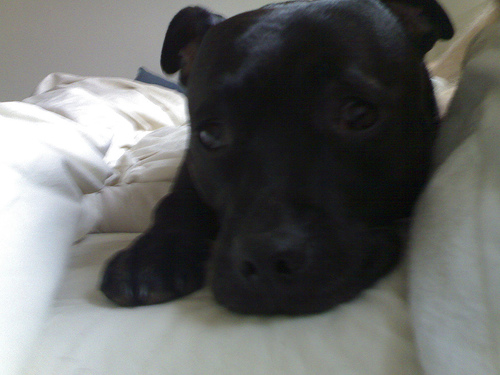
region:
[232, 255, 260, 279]
black nostril on dog's face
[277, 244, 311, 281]
round hole in dog's nostril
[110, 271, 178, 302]
black paws on dog's foot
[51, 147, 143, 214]
white creases in dog's bed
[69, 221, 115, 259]
edge of dog's bed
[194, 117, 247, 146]
dog's black eye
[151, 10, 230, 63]
dog's black floppy ear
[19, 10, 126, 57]
light gray wall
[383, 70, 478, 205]
side of dog's face resting on bed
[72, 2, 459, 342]
large black shaggy dog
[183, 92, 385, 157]
dark sad eyes of blurry puppy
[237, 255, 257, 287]
shadowed black+blurry nostril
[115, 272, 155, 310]
light reflecting off 2 dog's nails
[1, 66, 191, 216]
light reflecting off crumpled white bedding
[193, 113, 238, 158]
light reflecting on black puppy eye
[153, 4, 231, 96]
curled sweet puppy ear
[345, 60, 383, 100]
puppy eyebrow is slightly lighter than surrounding fur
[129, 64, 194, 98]
dark colored pillow in the photo's distance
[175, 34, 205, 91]
dark brown near ear of black puppy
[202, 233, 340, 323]
a black puppy's small muzzle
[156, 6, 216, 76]
The dog's left ear.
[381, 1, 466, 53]
The dog's right ear.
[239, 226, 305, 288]
The dog's nose and nostrils.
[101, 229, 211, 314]
The dog's left paw and nails.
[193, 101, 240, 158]
The black dog's left eye.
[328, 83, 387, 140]
The black dog's right eye.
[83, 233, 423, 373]
The white sheet the dog's paw and mouth is resting on.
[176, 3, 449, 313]
The black dog's head resting on the bed.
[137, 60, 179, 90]
The dark blue pillow in the background.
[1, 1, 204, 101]
The gray wall in the background.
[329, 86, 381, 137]
the right eye of a dog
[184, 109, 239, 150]
the left eye of a dog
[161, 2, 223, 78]
the ear of a dog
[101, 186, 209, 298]
the leg of a dog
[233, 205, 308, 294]
the nose of a dog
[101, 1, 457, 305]
a cute black dog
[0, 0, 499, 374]
a dog in a bed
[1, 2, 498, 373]
a bed with white sheets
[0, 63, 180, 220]
pillows in a bed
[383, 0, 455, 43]
the right ear of a dog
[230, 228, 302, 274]
nose of a black dog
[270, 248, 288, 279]
left nose hole of the dog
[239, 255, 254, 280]
right nose hole of the dog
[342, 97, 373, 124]
left eye of dog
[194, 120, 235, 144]
right eye of a dog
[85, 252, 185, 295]
left paw of the dog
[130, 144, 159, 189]
part of a white sheet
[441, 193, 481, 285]
part of a white pillow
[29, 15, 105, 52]
section of a white wall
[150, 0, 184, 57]
part of a right ear of a dog